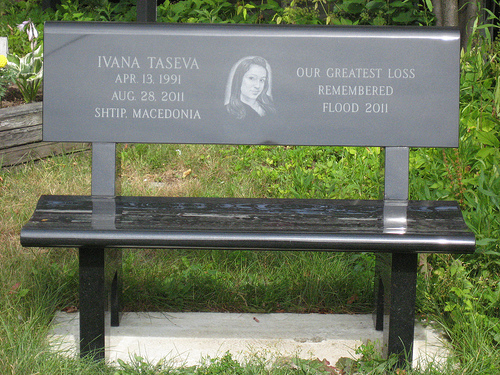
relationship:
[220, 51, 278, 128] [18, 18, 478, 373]
girl pictured on bench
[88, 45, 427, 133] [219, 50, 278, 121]
remembrance of girl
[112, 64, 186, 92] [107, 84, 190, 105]
birth date and death date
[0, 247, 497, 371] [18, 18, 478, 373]
grass growing around bench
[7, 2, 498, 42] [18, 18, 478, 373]
bushes growing around bench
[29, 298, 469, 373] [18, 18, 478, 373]
cement slab under bench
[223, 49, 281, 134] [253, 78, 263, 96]
lady has nose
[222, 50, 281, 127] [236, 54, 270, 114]
lady has head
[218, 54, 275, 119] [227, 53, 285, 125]
woman has hair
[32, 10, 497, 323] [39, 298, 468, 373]
bench on top of cement slab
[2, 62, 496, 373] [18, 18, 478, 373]
grass growing around bench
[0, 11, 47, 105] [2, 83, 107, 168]
plants in planter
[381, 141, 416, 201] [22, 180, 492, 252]
back supports reflection across seat